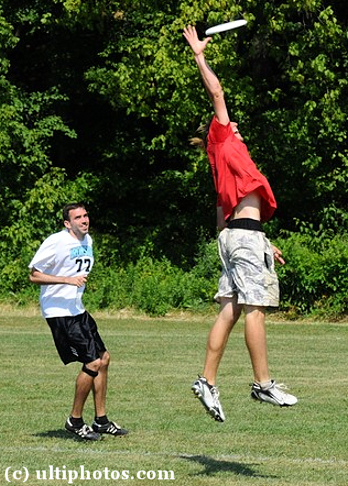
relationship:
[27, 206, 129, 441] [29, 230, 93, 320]
man wearing t shirt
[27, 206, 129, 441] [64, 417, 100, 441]
man wearing sneaker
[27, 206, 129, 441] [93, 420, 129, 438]
man wearing sneaker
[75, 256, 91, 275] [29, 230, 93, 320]
number on t shirt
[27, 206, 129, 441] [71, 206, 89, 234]
man has face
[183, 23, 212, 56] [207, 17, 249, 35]
hand catching frisbee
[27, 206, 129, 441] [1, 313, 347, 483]
man on field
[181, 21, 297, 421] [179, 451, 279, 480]
man has shadow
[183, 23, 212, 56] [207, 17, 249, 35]
hand reaching for frisbee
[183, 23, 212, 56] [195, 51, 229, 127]
hand on arm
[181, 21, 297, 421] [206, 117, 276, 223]
man wearing t shirt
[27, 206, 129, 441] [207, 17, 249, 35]
man playing frisbee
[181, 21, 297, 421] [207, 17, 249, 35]
man playing frisbee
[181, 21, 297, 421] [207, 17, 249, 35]
man jumping for frisbee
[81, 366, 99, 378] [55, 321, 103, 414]
band around leg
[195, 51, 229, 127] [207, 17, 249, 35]
arm reaching for frisbee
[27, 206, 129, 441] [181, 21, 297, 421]
man watching man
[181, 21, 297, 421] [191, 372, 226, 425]
man wearing shoe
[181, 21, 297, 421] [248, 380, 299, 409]
man wearing shoe